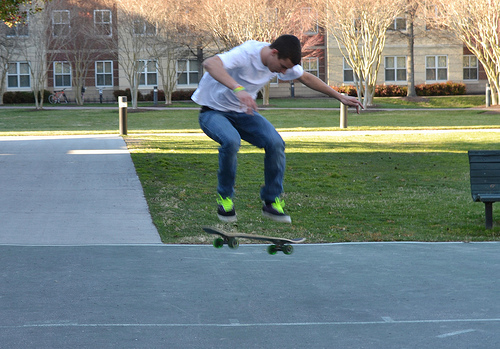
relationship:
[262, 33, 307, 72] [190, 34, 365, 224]
head of man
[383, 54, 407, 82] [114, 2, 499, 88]
window on a building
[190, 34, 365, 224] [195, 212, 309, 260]
man jumping on skateboard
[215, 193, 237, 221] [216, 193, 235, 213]
shoe with laces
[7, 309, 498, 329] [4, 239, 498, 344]
white lines on pavement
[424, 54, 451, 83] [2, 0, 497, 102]
window on a building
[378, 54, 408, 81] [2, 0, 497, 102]
window on a building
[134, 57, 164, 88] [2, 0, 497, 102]
window on a building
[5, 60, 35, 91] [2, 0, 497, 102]
window on a building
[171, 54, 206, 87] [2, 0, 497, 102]
window on a building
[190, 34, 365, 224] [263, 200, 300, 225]
man wearing shoe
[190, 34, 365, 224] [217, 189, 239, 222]
man wearing shoe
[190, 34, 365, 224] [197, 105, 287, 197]
man wearing jeans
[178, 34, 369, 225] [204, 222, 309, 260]
man on a skateboard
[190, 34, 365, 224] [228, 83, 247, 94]
man with a band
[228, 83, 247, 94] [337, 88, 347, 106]
band on h wrist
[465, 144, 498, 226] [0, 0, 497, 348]
bench in a park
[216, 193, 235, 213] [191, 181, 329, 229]
laces in sneakers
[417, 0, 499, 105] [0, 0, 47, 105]
tree of a building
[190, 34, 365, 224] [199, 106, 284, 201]
man wearing jeans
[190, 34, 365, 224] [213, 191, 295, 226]
man wearing sneakers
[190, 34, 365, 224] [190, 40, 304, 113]
man wearing shirt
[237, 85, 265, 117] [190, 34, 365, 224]
hand on man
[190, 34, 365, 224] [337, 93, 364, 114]
man has hand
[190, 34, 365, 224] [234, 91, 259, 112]
man has hand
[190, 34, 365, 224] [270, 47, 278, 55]
man has ear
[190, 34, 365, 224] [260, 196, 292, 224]
man wears shoe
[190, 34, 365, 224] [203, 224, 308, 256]
man jumps off skateboard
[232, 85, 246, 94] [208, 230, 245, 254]
band has tires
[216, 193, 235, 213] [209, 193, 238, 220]
laces on sneakers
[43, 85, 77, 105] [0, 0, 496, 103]
bike leaning against building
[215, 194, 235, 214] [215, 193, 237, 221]
laces on shoe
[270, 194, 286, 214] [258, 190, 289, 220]
laces on sneaker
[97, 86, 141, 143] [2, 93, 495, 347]
pole in ground